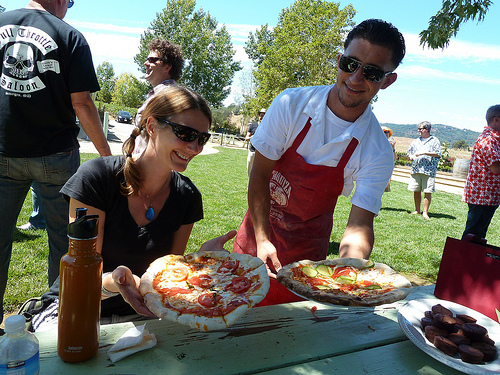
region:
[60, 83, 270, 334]
Woman is holding a pizza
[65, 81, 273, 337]
Woman is holding a pizza with two hands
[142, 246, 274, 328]
Pizza has tomatoes on it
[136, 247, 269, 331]
Pizza has slices of tomatoes on it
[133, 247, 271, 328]
Pizza has cheese on it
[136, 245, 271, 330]
Pizza has sauce on it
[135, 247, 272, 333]
Pizza has tomato sauce on it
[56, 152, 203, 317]
Woman is wearing a shirt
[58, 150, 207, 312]
Woman is wearing a black shirt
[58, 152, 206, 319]
Woman is wearing a v-neck shirt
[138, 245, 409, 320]
Two pizzas held side by side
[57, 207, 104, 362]
A tall orange container of liquids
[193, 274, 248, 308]
Pieces of tomato on top of the pizza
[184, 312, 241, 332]
The crust of the pizza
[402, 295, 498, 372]
A plate of brownies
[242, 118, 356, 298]
A red apron worn by a man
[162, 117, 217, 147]
A pair of sunglasses on a girl's face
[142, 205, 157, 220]
A large blue gem on a necklace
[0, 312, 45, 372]
The top of a water bottle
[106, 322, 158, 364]
A folded napkin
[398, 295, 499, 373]
A plate of dessert for the picnic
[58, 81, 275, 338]
A woman at a picnic table holding a pizza pie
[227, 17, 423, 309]
A man wearing an apron holding a pizza pie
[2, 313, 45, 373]
A bottle of water sitting on the picnic table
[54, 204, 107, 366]
A drink thermos sitting on the picnic table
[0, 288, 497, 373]
A picnic table with food and drink items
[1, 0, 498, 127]
A blue sky with clear weather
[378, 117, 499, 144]
Scenic mountains in the background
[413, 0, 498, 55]
Tree leaves hanging near the picnic table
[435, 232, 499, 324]
A red tote bag sitting near the picnic table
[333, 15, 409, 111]
Man wearing sun glasses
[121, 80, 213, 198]
Woman wearing sun glasses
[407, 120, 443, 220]
Man wearing hawaiian tshirt and glasses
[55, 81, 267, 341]
Woman holding pizza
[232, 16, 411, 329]
Man wearing apron holding pizza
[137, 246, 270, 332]
Cheese pizza with large tomatoes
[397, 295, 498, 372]
White plate with brownies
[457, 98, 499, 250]
Man wearing shirts with red and white pattern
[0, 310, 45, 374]
Bottle of water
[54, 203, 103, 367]
Large burnt orange water bottle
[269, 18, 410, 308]
Young man holding a pizza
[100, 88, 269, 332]
Young woman holding a pizza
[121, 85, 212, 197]
Woman with brown hair in a ponytail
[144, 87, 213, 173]
Young woman wearing sunglasses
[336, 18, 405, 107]
Young man wearing sunglasses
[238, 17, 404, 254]
Young man wearing a red apron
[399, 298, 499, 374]
Plate full of cupcake brownies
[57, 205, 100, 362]
Brown, aluminum water bottle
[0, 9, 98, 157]
Black t-shirt with a skull drawing on its back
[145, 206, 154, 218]
A woman's blue pendant